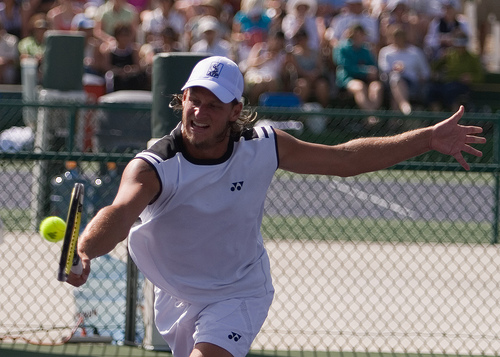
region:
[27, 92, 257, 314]
man hitting ball with racket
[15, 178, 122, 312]
yellow tennis ball and racket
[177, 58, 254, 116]
man wearing a white cap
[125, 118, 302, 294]
man wearing a white shirt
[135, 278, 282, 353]
man wearing white shorts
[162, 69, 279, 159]
man with long hair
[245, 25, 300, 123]
person sitting in audience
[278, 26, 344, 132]
person sitting in audience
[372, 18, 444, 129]
person sitting in audience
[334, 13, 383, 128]
person sitting in audience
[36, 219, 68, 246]
The ball bounces off the racket during tennis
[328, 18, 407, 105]
There is a large crowd for the tournamment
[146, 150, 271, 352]
Tennis players usually wear white clothes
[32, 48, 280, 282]
young man playing a tennis match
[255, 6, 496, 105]
Lots of people in the bleaches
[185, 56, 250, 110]
The baseball cap helps block the sun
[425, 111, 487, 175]
There is no wedding ring on his hand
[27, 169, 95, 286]
You need a ball and a racket to play tennis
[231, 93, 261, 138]
The mand has shoulder length hair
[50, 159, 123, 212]
The 5 gallon jugs go on the bubbler.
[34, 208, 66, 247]
The ball is yellow.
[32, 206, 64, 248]
The ball is round.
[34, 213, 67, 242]
The ball is small.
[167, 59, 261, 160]
The man is wearing a hat.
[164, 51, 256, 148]
The man has facial hair.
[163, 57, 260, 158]
The man's hair is blonde.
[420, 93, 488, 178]
The man has five fingers.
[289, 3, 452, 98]
The people in the background are blurry.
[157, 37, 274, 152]
the head of a man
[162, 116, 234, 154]
the teeth of a man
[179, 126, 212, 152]
the chin of a man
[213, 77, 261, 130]
the ear of a man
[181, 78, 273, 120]
the eyes of a man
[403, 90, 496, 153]
the hand of a man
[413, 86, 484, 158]
the thumb of a man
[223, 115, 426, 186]
the arm of a man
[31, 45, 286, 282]
a man playing tennis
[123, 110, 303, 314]
a man wearing a shirt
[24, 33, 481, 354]
Tennis player returning the ball backhanded.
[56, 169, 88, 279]
Yellow and black tennis racket.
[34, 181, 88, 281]
Yellow tennis ball in contact with racket.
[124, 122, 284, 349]
White and black tennis uniform.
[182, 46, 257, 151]
Tennis player wearing white cap.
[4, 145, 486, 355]
Metal fence behind tennis player.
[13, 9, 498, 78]
Audience watching the tennis match.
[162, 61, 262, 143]
Tennis player with long blonde hair.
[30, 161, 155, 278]
Tennis racket held in right hand.